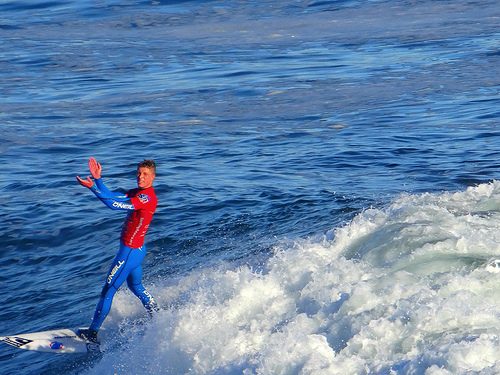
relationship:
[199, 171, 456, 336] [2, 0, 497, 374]
waves in sea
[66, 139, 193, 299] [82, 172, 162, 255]
man wearing shirt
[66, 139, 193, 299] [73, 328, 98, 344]
man wearing shoe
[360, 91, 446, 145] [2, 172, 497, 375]
waves in water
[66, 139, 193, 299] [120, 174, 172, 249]
man wearing shirt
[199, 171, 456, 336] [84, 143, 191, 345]
waves behind man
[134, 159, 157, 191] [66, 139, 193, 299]
hair on man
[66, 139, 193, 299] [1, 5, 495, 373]
man surfing in ocean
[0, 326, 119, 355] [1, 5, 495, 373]
surfboard in ocean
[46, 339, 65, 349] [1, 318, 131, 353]
sticker on surfboard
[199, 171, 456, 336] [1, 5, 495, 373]
waves in ocean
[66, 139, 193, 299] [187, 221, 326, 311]
man surfing on water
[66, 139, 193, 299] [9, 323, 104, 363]
man on surfboard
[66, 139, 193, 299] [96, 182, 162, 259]
man in wetsuit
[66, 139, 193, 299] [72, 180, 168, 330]
man in wetsuit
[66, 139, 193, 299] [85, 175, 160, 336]
man in wetsuit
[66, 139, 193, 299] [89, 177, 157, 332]
man in wet suit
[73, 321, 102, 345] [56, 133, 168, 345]
shoe on man